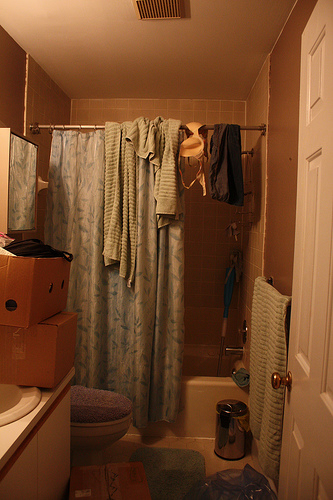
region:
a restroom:
[3, 42, 331, 493]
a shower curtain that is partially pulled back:
[44, 124, 224, 447]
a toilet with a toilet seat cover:
[67, 383, 135, 464]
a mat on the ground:
[127, 438, 206, 499]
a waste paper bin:
[207, 394, 254, 463]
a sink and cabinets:
[1, 368, 76, 498]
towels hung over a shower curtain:
[97, 110, 184, 312]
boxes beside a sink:
[0, 233, 75, 425]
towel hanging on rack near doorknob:
[245, 268, 294, 486]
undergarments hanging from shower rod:
[175, 117, 272, 211]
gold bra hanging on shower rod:
[180, 122, 209, 201]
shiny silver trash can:
[207, 397, 254, 463]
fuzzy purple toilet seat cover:
[70, 386, 134, 428]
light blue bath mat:
[132, 441, 201, 499]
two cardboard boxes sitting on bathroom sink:
[3, 247, 84, 395]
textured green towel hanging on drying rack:
[244, 275, 291, 477]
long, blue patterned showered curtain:
[49, 126, 181, 408]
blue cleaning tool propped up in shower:
[220, 256, 228, 391]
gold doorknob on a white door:
[271, 369, 298, 397]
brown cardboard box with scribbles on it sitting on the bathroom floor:
[67, 460, 152, 496]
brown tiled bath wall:
[75, 99, 236, 118]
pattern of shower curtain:
[50, 129, 93, 212]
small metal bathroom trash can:
[213, 399, 245, 456]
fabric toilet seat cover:
[70, 382, 128, 416]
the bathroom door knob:
[271, 372, 290, 386]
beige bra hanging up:
[178, 118, 205, 190]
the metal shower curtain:
[29, 117, 263, 133]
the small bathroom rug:
[133, 440, 205, 496]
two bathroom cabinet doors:
[10, 391, 67, 495]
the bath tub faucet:
[224, 344, 243, 355]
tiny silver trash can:
[208, 394, 252, 464]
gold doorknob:
[269, 370, 299, 389]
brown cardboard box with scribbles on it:
[65, 460, 153, 499]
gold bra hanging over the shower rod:
[178, 118, 212, 194]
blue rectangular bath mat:
[130, 443, 207, 499]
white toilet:
[69, 421, 130, 479]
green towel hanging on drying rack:
[248, 270, 288, 474]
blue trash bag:
[183, 464, 275, 499]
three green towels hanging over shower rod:
[90, 116, 185, 285]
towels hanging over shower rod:
[78, 105, 185, 279]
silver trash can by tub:
[205, 388, 254, 467]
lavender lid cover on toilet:
[69, 380, 137, 428]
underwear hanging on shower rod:
[177, 112, 259, 215]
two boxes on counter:
[3, 229, 86, 395]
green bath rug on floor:
[126, 442, 213, 498]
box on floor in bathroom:
[69, 461, 160, 498]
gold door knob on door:
[265, 360, 308, 400]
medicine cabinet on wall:
[0, 123, 47, 242]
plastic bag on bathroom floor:
[185, 460, 284, 499]